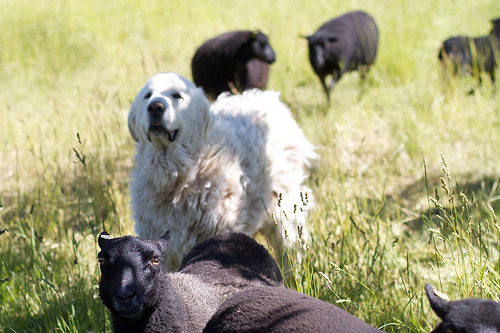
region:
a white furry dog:
[79, 73, 334, 260]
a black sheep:
[79, 226, 171, 310]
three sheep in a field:
[185, 10, 499, 98]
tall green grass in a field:
[364, 172, 493, 292]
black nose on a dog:
[135, 83, 183, 145]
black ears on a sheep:
[69, 222, 175, 324]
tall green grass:
[293, 168, 480, 286]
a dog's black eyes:
[133, 79, 195, 113]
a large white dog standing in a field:
[75, 60, 331, 280]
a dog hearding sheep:
[46, 34, 470, 322]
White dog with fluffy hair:
[124, 72, 314, 262]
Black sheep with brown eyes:
[88, 227, 276, 332]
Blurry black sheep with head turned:
[188, 27, 275, 94]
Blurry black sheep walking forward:
[302, 10, 384, 90]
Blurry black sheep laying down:
[439, 15, 499, 79]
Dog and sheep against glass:
[1, 2, 497, 328]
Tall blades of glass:
[406, 149, 498, 299]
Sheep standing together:
[190, 5, 499, 108]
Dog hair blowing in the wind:
[163, 71, 312, 257]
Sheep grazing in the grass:
[61, 223, 498, 328]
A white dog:
[62, 60, 376, 265]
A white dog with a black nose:
[45, 54, 304, 214]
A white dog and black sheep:
[74, 71, 308, 311]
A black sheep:
[46, 210, 283, 324]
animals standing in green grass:
[65, 19, 419, 270]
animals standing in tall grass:
[71, 26, 397, 315]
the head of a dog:
[83, 66, 242, 176]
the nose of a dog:
[141, 94, 189, 147]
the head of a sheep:
[66, 225, 186, 312]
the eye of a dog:
[165, 82, 200, 121]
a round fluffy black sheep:
[187, 24, 269, 91]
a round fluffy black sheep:
[302, 12, 387, 106]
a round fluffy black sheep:
[203, 267, 495, 332]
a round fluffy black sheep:
[91, 231, 288, 331]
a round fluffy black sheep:
[439, 18, 499, 89]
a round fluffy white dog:
[121, 69, 307, 254]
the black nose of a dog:
[146, 100, 161, 111]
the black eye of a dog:
[170, 88, 186, 99]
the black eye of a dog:
[143, 91, 152, 97]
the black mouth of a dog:
[143, 117, 178, 137]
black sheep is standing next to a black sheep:
[297, 1, 381, 110]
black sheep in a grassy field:
[1, 1, 498, 331]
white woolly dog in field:
[126, 71, 316, 266]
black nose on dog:
[147, 100, 164, 117]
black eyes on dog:
[172, 92, 184, 99]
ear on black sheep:
[324, 35, 338, 42]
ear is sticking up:
[424, 284, 447, 321]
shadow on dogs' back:
[208, 108, 278, 235]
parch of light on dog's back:
[212, 159, 248, 225]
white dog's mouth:
[143, 123, 181, 143]